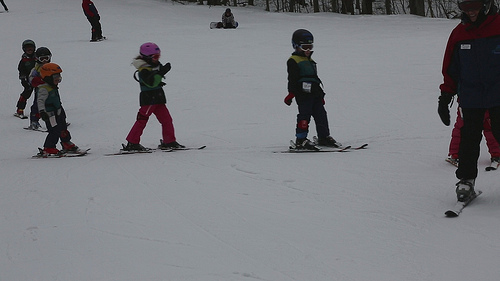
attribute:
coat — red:
[121, 63, 173, 98]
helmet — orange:
[36, 62, 61, 79]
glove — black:
[435, 95, 454, 125]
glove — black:
[281, 87, 298, 104]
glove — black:
[158, 61, 172, 78]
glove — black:
[33, 108, 50, 123]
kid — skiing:
[279, 24, 346, 149]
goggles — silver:
[298, 36, 348, 63]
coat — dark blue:
[440, 11, 499, 107]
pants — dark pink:
[159, 111, 174, 149]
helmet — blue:
[278, 21, 317, 54]